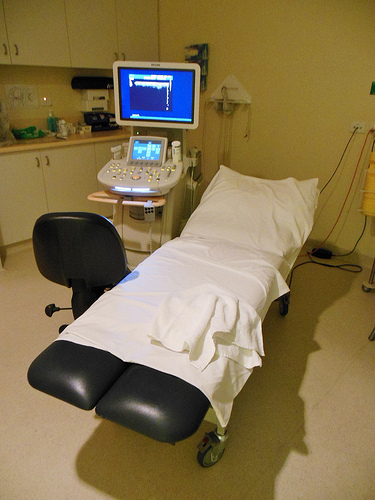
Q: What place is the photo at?
A: It is at the hospital.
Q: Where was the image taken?
A: It was taken at the hospital.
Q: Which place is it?
A: It is a hospital.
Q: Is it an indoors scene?
A: Yes, it is indoors.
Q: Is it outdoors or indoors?
A: It is indoors.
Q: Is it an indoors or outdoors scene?
A: It is indoors.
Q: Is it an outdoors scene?
A: No, it is indoors.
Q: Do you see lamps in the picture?
A: No, there are no lamps.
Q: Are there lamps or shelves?
A: No, there are no lamps or shelves.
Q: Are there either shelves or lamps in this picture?
A: No, there are no lamps or shelves.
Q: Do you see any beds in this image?
A: Yes, there is a bed.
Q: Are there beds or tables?
A: Yes, there is a bed.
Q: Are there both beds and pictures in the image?
A: No, there is a bed but no pictures.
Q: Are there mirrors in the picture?
A: No, there are no mirrors.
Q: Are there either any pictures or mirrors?
A: No, there are no mirrors or pictures.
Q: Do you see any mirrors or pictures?
A: No, there are no mirrors or pictures.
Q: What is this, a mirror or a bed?
A: This is a bed.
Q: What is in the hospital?
A: The bed is in the hospital.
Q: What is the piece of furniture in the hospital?
A: The piece of furniture is a bed.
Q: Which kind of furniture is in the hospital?
A: The piece of furniture is a bed.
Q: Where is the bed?
A: The bed is in the hospital.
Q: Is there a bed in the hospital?
A: Yes, there is a bed in the hospital.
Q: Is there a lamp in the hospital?
A: No, there is a bed in the hospital.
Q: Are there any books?
A: No, there are no books.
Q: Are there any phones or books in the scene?
A: No, there are no books or phones.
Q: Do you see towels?
A: Yes, there is a towel.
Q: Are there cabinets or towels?
A: Yes, there is a towel.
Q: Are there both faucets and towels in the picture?
A: No, there is a towel but no faucets.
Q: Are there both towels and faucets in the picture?
A: No, there is a towel but no faucets.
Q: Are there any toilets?
A: No, there are no toilets.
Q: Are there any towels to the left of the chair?
A: No, the towel is to the right of the chair.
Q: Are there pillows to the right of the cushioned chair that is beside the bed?
A: No, there is a towel to the right of the chair.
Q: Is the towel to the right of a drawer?
A: No, the towel is to the right of the chair.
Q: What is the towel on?
A: The towel is on the bed.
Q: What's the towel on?
A: The towel is on the bed.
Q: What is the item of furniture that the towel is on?
A: The piece of furniture is a bed.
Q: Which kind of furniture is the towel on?
A: The towel is on the bed.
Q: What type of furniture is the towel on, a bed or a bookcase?
A: The towel is on a bed.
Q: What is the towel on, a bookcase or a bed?
A: The towel is on a bed.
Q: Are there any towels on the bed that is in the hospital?
A: Yes, there is a towel on the bed.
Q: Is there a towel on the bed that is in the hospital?
A: Yes, there is a towel on the bed.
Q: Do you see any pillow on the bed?
A: No, there is a towel on the bed.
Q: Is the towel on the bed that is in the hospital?
A: Yes, the towel is on the bed.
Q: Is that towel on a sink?
A: No, the towel is on the bed.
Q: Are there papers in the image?
A: No, there are no papers.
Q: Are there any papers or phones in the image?
A: No, there are no papers or phones.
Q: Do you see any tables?
A: Yes, there is a table.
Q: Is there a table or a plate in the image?
A: Yes, there is a table.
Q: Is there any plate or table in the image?
A: Yes, there is a table.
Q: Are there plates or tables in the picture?
A: Yes, there is a table.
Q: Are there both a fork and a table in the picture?
A: No, there is a table but no forks.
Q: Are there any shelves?
A: No, there are no shelves.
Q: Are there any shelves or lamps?
A: No, there are no shelves or lamps.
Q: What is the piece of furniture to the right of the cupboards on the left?
A: The piece of furniture is a table.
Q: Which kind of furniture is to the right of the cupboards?
A: The piece of furniture is a table.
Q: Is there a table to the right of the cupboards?
A: Yes, there is a table to the right of the cupboards.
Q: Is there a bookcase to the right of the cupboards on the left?
A: No, there is a table to the right of the cupboards.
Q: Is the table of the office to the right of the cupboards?
A: Yes, the table is to the right of the cupboards.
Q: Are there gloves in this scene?
A: Yes, there are gloves.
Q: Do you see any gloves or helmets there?
A: Yes, there are gloves.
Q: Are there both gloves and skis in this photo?
A: No, there are gloves but no skis.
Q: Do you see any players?
A: No, there are no players.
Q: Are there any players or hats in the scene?
A: No, there are no players or hats.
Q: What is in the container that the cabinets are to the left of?
A: The gloves are in the box.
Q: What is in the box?
A: The gloves are in the box.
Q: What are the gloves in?
A: The gloves are in the box.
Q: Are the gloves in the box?
A: Yes, the gloves are in the box.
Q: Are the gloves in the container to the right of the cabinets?
A: Yes, the gloves are in the box.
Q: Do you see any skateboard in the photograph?
A: No, there are no skateboards.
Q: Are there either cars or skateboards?
A: No, there are no skateboards or cars.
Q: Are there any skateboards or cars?
A: No, there are no skateboards or cars.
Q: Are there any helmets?
A: No, there are no helmets.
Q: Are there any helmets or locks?
A: No, there are no helmets or locks.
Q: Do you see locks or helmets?
A: No, there are no helmets or locks.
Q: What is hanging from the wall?
A: The cords are hanging from the wall.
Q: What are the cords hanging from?
A: The cords are hanging from the wall.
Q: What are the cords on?
A: The wires are on the wall.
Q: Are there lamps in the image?
A: No, there are no lamps.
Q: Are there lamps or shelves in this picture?
A: No, there are no lamps or shelves.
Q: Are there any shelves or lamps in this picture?
A: No, there are no lamps or shelves.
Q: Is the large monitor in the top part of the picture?
A: Yes, the monitor is in the top of the image.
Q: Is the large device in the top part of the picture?
A: Yes, the monitor is in the top of the image.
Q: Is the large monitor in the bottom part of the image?
A: No, the monitor is in the top of the image.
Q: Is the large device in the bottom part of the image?
A: No, the monitor is in the top of the image.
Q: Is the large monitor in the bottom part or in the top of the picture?
A: The monitor is in the top of the image.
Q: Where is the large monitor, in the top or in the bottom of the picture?
A: The monitor is in the top of the image.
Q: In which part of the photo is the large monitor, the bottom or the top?
A: The monitor is in the top of the image.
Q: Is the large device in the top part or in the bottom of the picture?
A: The monitor is in the top of the image.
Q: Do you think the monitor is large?
A: Yes, the monitor is large.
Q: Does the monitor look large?
A: Yes, the monitor is large.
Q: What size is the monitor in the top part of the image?
A: The monitor is large.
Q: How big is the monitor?
A: The monitor is large.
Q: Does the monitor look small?
A: No, the monitor is large.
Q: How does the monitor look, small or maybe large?
A: The monitor is large.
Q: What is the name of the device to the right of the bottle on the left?
A: The device is a monitor.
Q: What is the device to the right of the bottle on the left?
A: The device is a monitor.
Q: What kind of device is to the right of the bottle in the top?
A: The device is a monitor.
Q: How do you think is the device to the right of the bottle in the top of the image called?
A: The device is a monitor.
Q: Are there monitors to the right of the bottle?
A: Yes, there is a monitor to the right of the bottle.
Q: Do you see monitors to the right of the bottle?
A: Yes, there is a monitor to the right of the bottle.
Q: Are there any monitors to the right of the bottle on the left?
A: Yes, there is a monitor to the right of the bottle.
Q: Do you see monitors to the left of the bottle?
A: No, the monitor is to the right of the bottle.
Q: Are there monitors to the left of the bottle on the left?
A: No, the monitor is to the right of the bottle.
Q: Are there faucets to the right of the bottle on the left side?
A: No, there is a monitor to the right of the bottle.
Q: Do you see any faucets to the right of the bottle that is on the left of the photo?
A: No, there is a monitor to the right of the bottle.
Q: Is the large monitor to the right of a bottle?
A: Yes, the monitor is to the right of a bottle.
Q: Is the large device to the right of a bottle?
A: Yes, the monitor is to the right of a bottle.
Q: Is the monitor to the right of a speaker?
A: No, the monitor is to the right of a bottle.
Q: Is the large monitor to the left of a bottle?
A: No, the monitor is to the right of a bottle.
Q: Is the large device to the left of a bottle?
A: No, the monitor is to the right of a bottle.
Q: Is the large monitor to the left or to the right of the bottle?
A: The monitor is to the right of the bottle.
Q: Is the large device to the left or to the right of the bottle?
A: The monitor is to the right of the bottle.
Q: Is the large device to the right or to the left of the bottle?
A: The monitor is to the right of the bottle.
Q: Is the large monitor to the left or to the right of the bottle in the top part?
A: The monitor is to the right of the bottle.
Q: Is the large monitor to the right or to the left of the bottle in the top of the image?
A: The monitor is to the right of the bottle.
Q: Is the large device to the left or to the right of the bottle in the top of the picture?
A: The monitor is to the right of the bottle.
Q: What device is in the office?
A: The device is a monitor.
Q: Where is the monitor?
A: The monitor is in the office.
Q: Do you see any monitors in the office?
A: Yes, there is a monitor in the office.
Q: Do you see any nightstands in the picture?
A: No, there are no nightstands.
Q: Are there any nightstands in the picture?
A: No, there are no nightstands.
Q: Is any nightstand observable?
A: No, there are no nightstands.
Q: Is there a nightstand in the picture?
A: No, there are no nightstands.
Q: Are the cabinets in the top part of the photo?
A: Yes, the cabinets are in the top of the image.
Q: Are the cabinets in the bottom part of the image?
A: No, the cabinets are in the top of the image.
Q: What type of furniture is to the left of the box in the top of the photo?
A: The pieces of furniture are cabinets.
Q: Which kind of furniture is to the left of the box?
A: The pieces of furniture are cabinets.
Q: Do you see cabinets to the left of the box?
A: Yes, there are cabinets to the left of the box.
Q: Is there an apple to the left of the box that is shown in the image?
A: No, there are cabinets to the left of the box.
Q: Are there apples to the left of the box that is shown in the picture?
A: No, there are cabinets to the left of the box.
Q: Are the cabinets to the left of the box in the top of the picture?
A: Yes, the cabinets are to the left of the box.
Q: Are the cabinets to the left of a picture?
A: No, the cabinets are to the left of the box.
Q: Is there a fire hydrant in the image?
A: No, there are no fire hydrants.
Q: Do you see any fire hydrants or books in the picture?
A: No, there are no fire hydrants or books.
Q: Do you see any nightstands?
A: No, there are no nightstands.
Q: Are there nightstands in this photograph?
A: No, there are no nightstands.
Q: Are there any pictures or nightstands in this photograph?
A: No, there are no nightstands or pictures.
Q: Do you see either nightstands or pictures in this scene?
A: No, there are no nightstands or pictures.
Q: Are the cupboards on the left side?
A: Yes, the cupboards are on the left of the image.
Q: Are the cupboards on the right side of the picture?
A: No, the cupboards are on the left of the image.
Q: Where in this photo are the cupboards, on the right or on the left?
A: The cupboards are on the left of the image.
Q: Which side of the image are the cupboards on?
A: The cupboards are on the left of the image.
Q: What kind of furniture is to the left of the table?
A: The pieces of furniture are cupboards.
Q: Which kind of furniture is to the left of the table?
A: The pieces of furniture are cupboards.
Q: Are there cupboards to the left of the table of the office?
A: Yes, there are cupboards to the left of the table.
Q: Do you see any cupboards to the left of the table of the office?
A: Yes, there are cupboards to the left of the table.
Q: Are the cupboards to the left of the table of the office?
A: Yes, the cupboards are to the left of the table.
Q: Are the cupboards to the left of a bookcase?
A: No, the cupboards are to the left of the table.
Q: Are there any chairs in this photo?
A: Yes, there is a chair.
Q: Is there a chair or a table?
A: Yes, there is a chair.